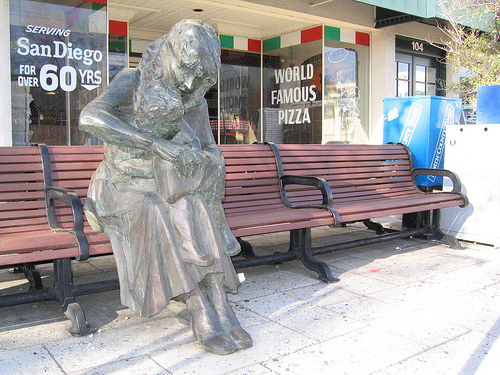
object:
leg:
[53, 257, 99, 339]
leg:
[291, 229, 336, 284]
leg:
[428, 209, 463, 252]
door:
[395, 53, 411, 96]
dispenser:
[382, 95, 462, 193]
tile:
[280, 280, 365, 309]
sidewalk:
[0, 213, 499, 375]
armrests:
[407, 168, 461, 195]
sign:
[335, 70, 365, 132]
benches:
[0, 143, 471, 336]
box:
[438, 123, 499, 250]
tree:
[424, 0, 499, 122]